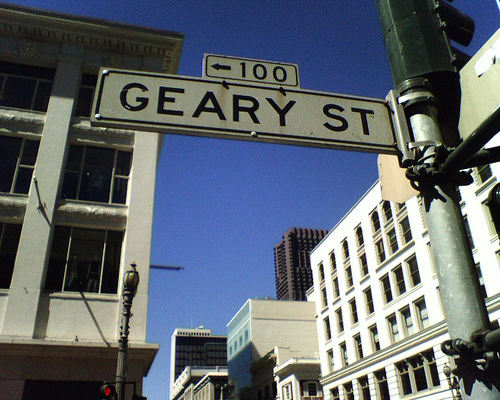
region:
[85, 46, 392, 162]
black and white street signs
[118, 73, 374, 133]
black lettering on white sign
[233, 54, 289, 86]
black numbers on white background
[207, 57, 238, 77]
black arrow on white sign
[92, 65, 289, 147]
bolts holding the sign together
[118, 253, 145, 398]
grey pole with street lamp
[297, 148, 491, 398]
white building on the right side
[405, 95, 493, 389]
pole street sign is attached to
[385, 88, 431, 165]
bracket attaching sign to pole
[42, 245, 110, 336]
shadow on the buildling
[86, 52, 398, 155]
Black and white sign.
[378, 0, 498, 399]
Gray metal sign post.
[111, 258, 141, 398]
Tall metal street light.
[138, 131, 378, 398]
Area of blue sky.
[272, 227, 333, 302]
Large tall brown building.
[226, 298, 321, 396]
Large ivory colored building.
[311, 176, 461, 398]
Building with many windows.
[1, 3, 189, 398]
A large gray building.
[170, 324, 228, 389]
Black and white building.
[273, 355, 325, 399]
Brown and white building.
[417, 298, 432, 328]
window on the building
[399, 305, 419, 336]
window on the building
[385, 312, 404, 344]
window on the building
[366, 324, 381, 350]
window on the building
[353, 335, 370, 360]
window on the building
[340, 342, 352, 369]
window on the building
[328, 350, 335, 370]
window on the building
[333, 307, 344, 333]
window on the building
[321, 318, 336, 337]
window on the building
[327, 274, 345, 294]
window on the building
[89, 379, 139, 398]
LIGHT SEEN TRAFFIC LIGHT IS RED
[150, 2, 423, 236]
SKY IS BLUE AND CLOUDLESS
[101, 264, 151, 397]
TALL POLE IN FRONT OF BUILDING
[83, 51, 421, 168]
STREET SIGN INDICATES THIS IS GEARY ST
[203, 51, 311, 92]
ARROW IS SEEN ON SMALL STREET SIGN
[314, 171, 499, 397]
LARGE BUILDING WITH MULTIBLE WINDOWS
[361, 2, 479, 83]
STREET LIGHT ON TOP OF POLE OVER STREET SIGN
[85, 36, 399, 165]
STREET SIGN IS WHITE WITH BLACK LETTERING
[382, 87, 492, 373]
POLE IS MADE OF METAL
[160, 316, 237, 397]
BUILDING IN BACKGROUND IS WHITE WITH BLACK WINDOW AREA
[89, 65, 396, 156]
Directional street sign with black letters.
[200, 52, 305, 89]
Small directional street sign with numbers.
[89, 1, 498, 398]
Directional street signs attached to electric signal.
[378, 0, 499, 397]
Electric signal with large bolts.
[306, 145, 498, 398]
Tall brick white building with many windows.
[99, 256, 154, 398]
Electric signal with electric ball on top.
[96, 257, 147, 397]
Red light on electric signal.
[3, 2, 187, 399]
Tall off white building with old windows.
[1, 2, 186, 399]
Tall off white building with decorative awning.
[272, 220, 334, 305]
Tall brown building with many windows.